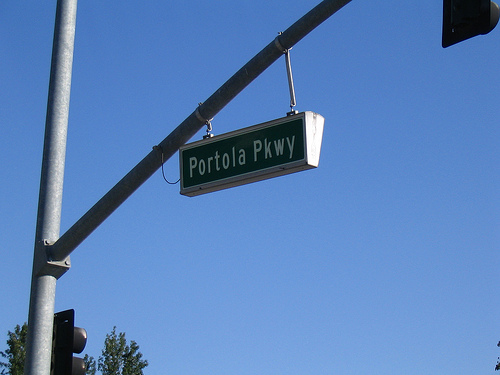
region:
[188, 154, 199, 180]
white letter on sign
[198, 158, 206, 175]
white letter on sign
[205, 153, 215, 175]
white letter on sign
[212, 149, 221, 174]
white letter on sign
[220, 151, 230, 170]
white letter on sign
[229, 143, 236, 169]
white letter on sign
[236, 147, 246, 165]
white letter on sign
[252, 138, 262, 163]
white letter on sign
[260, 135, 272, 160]
white letter on sign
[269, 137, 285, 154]
white letter on sign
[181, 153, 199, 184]
The letter is white.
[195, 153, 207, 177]
The letter is white.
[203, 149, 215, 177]
The letter is white.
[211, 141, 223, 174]
The letter is white.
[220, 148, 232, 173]
The letter is white.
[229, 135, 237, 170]
The letter is white.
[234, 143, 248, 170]
The letter is white.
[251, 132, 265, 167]
The letter is white.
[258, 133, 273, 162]
The letter is white.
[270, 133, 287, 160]
The letter is white.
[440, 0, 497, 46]
bottom of traffic light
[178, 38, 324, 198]
sign hanging on pole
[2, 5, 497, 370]
blue of daytime sky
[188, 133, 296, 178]
white words on sign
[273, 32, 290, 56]
brace around metal pole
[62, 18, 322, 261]
horizontal pole tilted up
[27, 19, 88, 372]
traffic light on pole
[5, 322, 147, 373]
leaves on tree tops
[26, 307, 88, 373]
traffic light on pole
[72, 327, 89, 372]
covers over street lights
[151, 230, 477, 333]
The sky is clear and blue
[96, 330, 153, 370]
The leaves are the color green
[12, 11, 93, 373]
The pole is made of metal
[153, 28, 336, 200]
The sign on the pole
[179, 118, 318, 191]
The color of the sign is green and white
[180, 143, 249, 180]
The word says "Portola"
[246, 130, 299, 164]
The word says "Pkwy"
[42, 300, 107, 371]
The street light is the color black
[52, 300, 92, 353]
The top of the street light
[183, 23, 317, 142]
The clamps to the on the pole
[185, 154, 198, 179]
one white lettered capital P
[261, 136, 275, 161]
one lowercase white k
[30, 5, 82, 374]
one light gray metal pole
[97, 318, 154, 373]
top of green tree against blue sky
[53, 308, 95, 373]
back of black metal traffic light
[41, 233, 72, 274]
two metal bolts for metal pole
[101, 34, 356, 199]
street sign suspended over metal pole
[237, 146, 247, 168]
one white lowercase letter a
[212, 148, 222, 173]
one white lowercase letter t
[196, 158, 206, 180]
one white lowercase letter o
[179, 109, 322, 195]
a street sign suspended over a street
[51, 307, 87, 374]
traffic light on a metal pole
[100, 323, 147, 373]
the top of a tree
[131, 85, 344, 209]
sign above the street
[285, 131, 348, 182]
corner of the sign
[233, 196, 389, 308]
blue sky with no clouds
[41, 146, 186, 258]
pole next to sign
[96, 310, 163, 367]
leaves on the tree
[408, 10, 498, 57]
light above the street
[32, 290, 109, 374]
light on a silver pole